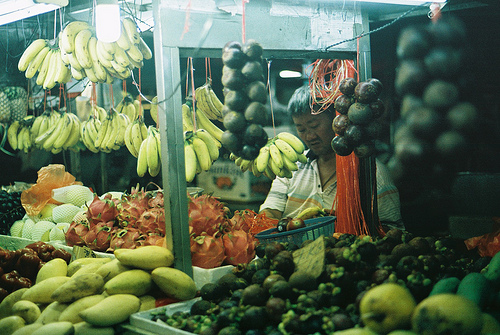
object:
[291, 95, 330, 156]
man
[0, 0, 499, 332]
fruit stand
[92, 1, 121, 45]
light bulb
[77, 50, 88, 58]
banana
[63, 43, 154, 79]
bunch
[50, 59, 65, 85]
banana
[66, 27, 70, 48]
banana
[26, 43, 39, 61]
banana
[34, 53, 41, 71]
banana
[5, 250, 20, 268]
pepper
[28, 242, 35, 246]
pepper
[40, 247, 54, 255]
pepper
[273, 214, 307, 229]
fruit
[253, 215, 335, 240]
bowl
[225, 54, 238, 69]
fruit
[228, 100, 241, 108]
fruit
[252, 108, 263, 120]
fruit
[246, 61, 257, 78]
fruit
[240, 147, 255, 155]
fruit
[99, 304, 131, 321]
vegetable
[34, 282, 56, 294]
vegetable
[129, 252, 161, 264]
vegetable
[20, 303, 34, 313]
vegetable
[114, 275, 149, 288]
vegetable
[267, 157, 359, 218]
shirt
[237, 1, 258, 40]
cord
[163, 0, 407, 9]
ceiling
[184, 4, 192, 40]
cord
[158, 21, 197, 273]
pole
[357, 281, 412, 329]
mango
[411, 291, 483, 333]
mango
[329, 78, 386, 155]
avacado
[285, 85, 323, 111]
hair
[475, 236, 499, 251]
bag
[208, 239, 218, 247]
spike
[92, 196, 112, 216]
fruit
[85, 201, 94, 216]
spike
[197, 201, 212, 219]
fruit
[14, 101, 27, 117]
pinapple